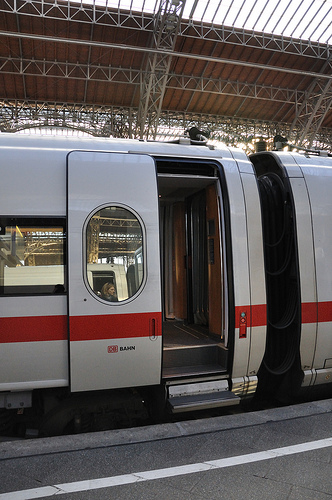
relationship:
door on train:
[154, 158, 232, 379] [0, 135, 268, 409]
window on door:
[78, 201, 148, 307] [154, 158, 232, 379]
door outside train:
[154, 158, 232, 379] [0, 135, 268, 409]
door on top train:
[154, 158, 232, 379] [0, 135, 268, 409]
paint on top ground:
[160, 420, 301, 484] [9, 396, 313, 489]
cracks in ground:
[198, 461, 310, 495] [0, 399, 332, 500]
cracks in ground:
[24, 470, 60, 492] [0, 399, 332, 500]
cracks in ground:
[190, 461, 296, 498] [0, 399, 332, 500]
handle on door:
[136, 311, 161, 346] [69, 153, 163, 392]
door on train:
[69, 153, 163, 392] [0, 135, 268, 409]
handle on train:
[136, 311, 161, 346] [0, 135, 268, 409]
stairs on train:
[159, 344, 240, 409] [4, 97, 330, 412]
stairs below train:
[159, 344, 240, 409] [4, 97, 330, 412]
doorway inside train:
[149, 151, 235, 386] [4, 97, 330, 412]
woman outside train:
[87, 265, 129, 317] [9, 100, 329, 386]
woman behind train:
[87, 265, 129, 317] [9, 100, 329, 386]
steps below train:
[161, 348, 236, 411] [4, 97, 330, 412]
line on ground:
[3, 435, 320, 488] [0, 399, 332, 500]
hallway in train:
[157, 176, 227, 367] [43, 123, 264, 311]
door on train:
[69, 153, 163, 392] [4, 97, 330, 412]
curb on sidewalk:
[1, 396, 331, 458] [0, 411, 331, 499]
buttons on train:
[233, 300, 258, 344] [221, 155, 265, 385]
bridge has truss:
[3, 0, 332, 138] [127, 14, 143, 27]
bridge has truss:
[3, 3, 324, 130] [178, 24, 198, 39]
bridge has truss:
[3, 0, 332, 138] [241, 30, 252, 46]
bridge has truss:
[3, 0, 332, 138] [257, 85, 262, 95]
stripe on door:
[1, 295, 330, 345] [62, 147, 166, 402]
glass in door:
[85, 207, 144, 303] [69, 153, 163, 392]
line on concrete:
[0, 435, 332, 500] [1, 401, 329, 498]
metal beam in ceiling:
[132, 52, 171, 130] [53, 11, 301, 121]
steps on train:
[161, 348, 236, 411] [2, 121, 329, 443]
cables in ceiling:
[135, 0, 188, 139] [0, 0, 331, 151]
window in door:
[78, 201, 148, 307] [62, 147, 166, 402]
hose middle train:
[257, 167, 305, 388] [2, 130, 330, 400]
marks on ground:
[173, 420, 188, 439] [0, 399, 332, 500]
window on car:
[78, 201, 148, 307] [1, 130, 331, 435]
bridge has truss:
[3, 0, 332, 138] [101, 64, 129, 77]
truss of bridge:
[225, 31, 230, 38] [220, 29, 294, 71]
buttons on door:
[238, 300, 250, 344] [69, 153, 163, 392]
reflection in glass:
[90, 211, 143, 303] [85, 207, 144, 303]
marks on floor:
[170, 322, 202, 338] [163, 318, 234, 375]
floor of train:
[163, 318, 234, 375] [2, 121, 329, 443]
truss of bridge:
[77, 61, 104, 79] [3, 3, 324, 130]